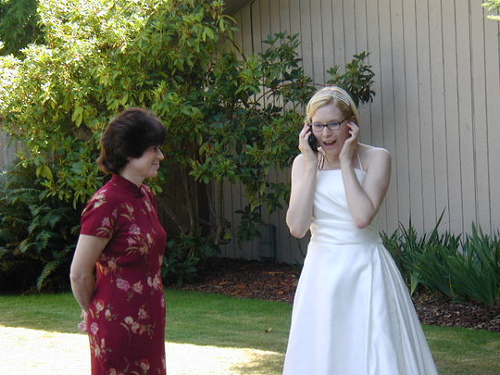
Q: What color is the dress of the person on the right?
A: White.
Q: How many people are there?
A: Two.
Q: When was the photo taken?
A: Daytime.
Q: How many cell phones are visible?
A: One.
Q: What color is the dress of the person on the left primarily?
A: Red.